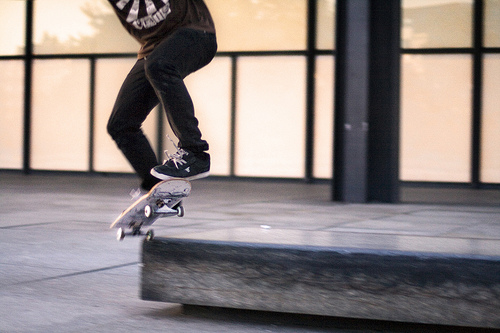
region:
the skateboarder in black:
[112, 2, 223, 182]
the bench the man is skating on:
[141, 217, 498, 327]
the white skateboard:
[107, 178, 189, 245]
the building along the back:
[7, 1, 497, 181]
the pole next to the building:
[331, 5, 403, 200]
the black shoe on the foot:
[149, 146, 214, 178]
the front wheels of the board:
[140, 202, 182, 224]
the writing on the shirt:
[111, 0, 178, 27]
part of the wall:
[33, 56, 89, 179]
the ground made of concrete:
[7, 180, 139, 327]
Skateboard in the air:
[100, 177, 192, 257]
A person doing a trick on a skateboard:
[96, 4, 226, 249]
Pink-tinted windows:
[1, 3, 106, 172]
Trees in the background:
[32, 1, 113, 59]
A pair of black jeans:
[103, 27, 213, 150]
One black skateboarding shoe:
[142, 146, 214, 183]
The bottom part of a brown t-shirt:
[85, 0, 215, 39]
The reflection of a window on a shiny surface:
[206, 223, 329, 248]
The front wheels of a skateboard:
[142, 198, 201, 220]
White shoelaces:
[160, 135, 193, 173]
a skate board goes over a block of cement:
[109, 174, 497, 327]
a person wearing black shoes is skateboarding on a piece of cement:
[108, 130, 498, 317]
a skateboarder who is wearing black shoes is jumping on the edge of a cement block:
[112, 125, 487, 241]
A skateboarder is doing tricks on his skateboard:
[102, 82, 204, 226]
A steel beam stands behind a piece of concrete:
[317, 25, 496, 325]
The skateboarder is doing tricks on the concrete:
[107, 50, 496, 325]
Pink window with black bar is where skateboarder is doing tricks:
[210, 59, 322, 173]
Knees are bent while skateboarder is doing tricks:
[103, 47, 218, 241]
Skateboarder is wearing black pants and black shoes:
[95, 23, 231, 236]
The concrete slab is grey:
[134, 227, 496, 329]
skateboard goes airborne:
[89, 157, 202, 244]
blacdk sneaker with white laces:
[149, 135, 215, 180]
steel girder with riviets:
[336, 0, 398, 211]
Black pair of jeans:
[92, 27, 221, 150]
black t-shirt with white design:
[108, 2, 220, 41]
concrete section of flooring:
[0, 170, 125, 323]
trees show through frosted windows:
[9, 2, 114, 85]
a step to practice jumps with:
[144, 201, 479, 332]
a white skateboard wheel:
[137, 197, 160, 221]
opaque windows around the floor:
[2, 52, 115, 179]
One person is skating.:
[59, 52, 266, 229]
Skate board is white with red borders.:
[93, 169, 195, 251]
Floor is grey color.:
[31, 208, 420, 315]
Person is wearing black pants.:
[78, 46, 228, 156]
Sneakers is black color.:
[98, 133, 215, 217]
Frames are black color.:
[16, 18, 483, 187]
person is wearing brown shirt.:
[106, 4, 233, 53]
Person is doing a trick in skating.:
[85, 28, 244, 283]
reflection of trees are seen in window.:
[8, 12, 355, 146]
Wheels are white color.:
[110, 191, 208, 248]